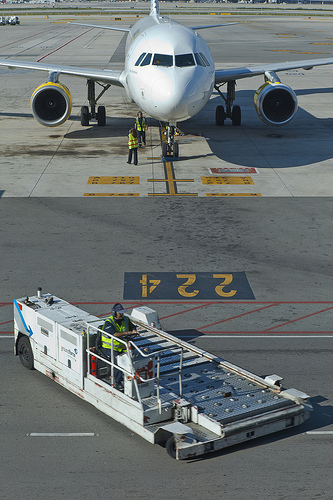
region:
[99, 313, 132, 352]
Bright colored safety vest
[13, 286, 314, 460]
Heavy machinery driven by man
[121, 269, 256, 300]
Numbers on airport tarmac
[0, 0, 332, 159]
Airplane parked on tarmac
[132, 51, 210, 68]
Windows on front of plane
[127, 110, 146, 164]
Two workers standing under plane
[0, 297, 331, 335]
Red lines on pavement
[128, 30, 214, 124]
Cockpit of airplane is white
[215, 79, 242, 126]
Piece of airplane landing gear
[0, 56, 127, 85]
Wing of the airplane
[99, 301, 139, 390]
man operating a piece of airport equipment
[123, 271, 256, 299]
number 2 2 4 painted on an airport lot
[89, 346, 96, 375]
red fire extinguisher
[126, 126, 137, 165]
female airport personnel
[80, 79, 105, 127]
airplane tire and landing gear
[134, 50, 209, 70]
front windows of an airplane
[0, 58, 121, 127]
airplane wing with an engine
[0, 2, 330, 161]
a large airplane sitting in a lot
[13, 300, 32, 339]
blue arrow painted on side of a white vehicle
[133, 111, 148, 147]
male airport worker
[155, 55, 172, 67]
WINDOW ON THE PLANE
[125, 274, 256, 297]
YELLOW NUMBERS ON THE GROUND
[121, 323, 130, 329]
MAN IN YELLOW VEST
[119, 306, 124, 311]
MAN HAS ON A HAT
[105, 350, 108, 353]
MAN WEARING BLUE JEANS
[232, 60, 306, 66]
WING OF THE PLANE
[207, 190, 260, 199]
YELLOW BLOCKS ON THE GROUND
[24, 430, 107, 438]
WHITE DOTTED LINES ON PAVEMENT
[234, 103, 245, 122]
BLACK WHEEL ON THE PLANE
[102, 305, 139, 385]
A person driving an airport vehicle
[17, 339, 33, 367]
A tire on the airport vehicle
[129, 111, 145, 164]
Men beneath the airplane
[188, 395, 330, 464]
A shadow on the ground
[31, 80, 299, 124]
Engines on the airplane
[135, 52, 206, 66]
A window on the airplane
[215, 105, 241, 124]
Wheels on the airplane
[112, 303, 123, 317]
The man is wearing earmuffs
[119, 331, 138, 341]
A steering wheel on the vehicle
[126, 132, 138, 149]
The person is wearing a vest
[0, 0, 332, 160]
plane on the tarmac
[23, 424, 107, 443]
white line on the ground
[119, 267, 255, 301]
yellow numbers on a black background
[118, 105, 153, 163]
people standing on the tarmac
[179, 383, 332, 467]
shadow on the ground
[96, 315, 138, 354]
silver and yellow traffic vest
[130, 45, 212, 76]
windows around the cockpit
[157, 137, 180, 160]
two wheels on the front of the plane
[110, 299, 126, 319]
headphones on the head